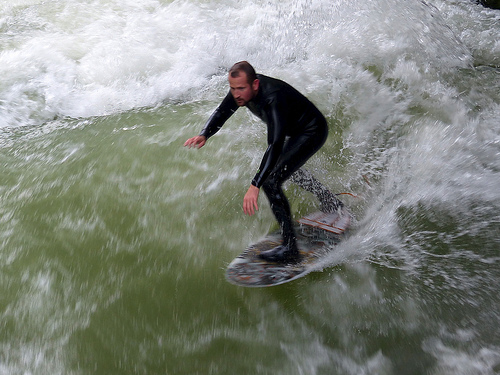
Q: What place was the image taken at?
A: It was taken at the ocean.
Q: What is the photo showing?
A: It is showing an ocean.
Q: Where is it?
A: This is at the ocean.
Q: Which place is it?
A: It is an ocean.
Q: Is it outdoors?
A: Yes, it is outdoors.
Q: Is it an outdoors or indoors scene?
A: It is outdoors.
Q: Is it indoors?
A: No, it is outdoors.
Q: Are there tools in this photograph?
A: No, there are no tools.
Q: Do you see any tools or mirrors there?
A: No, there are no tools or mirrors.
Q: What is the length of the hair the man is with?
A: The hair is short.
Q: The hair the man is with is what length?
A: The hair is short.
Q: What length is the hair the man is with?
A: The hair is short.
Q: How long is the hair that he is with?
A: The hair is short.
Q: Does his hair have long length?
A: No, the hair is short.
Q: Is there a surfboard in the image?
A: Yes, there is a surfboard.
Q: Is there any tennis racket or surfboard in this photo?
A: Yes, there is a surfboard.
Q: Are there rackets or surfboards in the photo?
A: Yes, there is a surfboard.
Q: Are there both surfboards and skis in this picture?
A: No, there is a surfboard but no skis.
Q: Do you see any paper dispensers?
A: No, there are no paper dispensers.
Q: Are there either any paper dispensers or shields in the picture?
A: No, there are no paper dispensers or shields.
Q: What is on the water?
A: The surfboard is on the water.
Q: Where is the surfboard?
A: The surfboard is on the water.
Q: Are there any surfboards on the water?
A: Yes, there is a surfboard on the water.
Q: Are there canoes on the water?
A: No, there is a surfboard on the water.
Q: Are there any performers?
A: No, there are no performers.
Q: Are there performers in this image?
A: No, there are no performers.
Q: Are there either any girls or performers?
A: No, there are no performers or girls.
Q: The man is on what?
A: The man is on the surfboard.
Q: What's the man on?
A: The man is on the surfboard.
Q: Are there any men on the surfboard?
A: Yes, there is a man on the surfboard.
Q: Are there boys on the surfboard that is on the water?
A: No, there is a man on the surfboard.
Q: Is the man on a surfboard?
A: Yes, the man is on a surfboard.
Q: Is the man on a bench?
A: No, the man is on a surfboard.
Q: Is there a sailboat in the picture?
A: No, there are no sailboats.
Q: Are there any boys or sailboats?
A: No, there are no sailboats or boys.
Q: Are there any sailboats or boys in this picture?
A: No, there are no sailboats or boys.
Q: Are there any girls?
A: No, there are no girls.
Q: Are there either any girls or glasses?
A: No, there are no girls or glasses.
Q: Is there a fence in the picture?
A: No, there are no fences.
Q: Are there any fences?
A: No, there are no fences.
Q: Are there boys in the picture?
A: No, there are no boys.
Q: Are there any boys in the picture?
A: No, there are no boys.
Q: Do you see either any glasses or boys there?
A: No, there are no boys or glasses.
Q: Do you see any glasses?
A: No, there are no glasses.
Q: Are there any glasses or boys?
A: No, there are no glasses or boys.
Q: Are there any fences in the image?
A: No, there are no fences.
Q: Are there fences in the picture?
A: No, there are no fences.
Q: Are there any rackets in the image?
A: No, there are no rackets.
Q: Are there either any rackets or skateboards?
A: No, there are no rackets or skateboards.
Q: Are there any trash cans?
A: No, there are no trash cans.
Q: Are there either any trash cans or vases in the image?
A: No, there are no trash cans or vases.